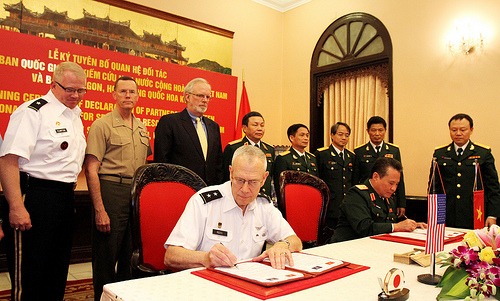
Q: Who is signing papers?
A: Military officials.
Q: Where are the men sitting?
A: In red chairs at a table.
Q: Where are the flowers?
A: On the table.